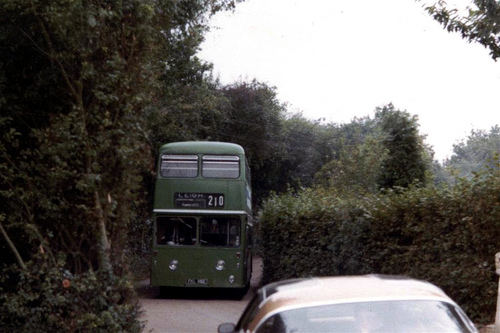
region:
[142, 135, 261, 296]
green bus on a road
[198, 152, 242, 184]
window on a bus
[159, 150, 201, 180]
window on a bus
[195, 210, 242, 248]
window on a bus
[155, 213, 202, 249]
window on a bus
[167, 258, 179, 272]
headlight on a bus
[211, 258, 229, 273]
headlight on a bus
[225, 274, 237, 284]
headlight on a bus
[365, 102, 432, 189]
tree with green leaves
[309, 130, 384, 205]
tree with green leaves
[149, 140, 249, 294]
green bus on road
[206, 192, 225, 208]
writing in white on bus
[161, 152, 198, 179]
white top part of bus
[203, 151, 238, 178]
white top part of bus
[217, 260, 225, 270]
head light on bus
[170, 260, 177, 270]
head light on bus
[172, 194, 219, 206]
black part on bus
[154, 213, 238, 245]
front window of bus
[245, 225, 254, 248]
side mirror of bus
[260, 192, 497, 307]
green hedges by row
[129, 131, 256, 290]
green double decker bus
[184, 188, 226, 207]
white numbers on bus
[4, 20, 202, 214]
green trees overhang bus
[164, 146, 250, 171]
white blinds in bus windows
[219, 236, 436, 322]
car in front of bus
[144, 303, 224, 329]
light grey pavement under bus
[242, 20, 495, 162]
sky is grey and cloudy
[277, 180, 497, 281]
green bush next to bus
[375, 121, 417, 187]
pine trees behind bushes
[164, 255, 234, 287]
white headlights on bus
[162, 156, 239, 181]
A windscreen on the bus.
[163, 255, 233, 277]
Headlights on the bus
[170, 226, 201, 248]
Wipers on the bus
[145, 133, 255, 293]
A bus on the road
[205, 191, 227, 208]
Numbers written on the bus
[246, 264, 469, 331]
A car in the foreground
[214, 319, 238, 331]
A side mirror on the car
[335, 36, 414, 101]
Cloudy skies in the background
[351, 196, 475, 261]
A hedge in the photo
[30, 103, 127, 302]
Trees on the roadside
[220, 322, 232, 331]
mirror on car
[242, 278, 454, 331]
roof of brown car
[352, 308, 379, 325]
head of person in car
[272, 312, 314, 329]
head of person in car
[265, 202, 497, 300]
green hedge by road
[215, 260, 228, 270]
light on green bus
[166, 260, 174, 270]
light on green bus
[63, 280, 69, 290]
flower on green shrub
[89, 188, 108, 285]
trunk of tree by road